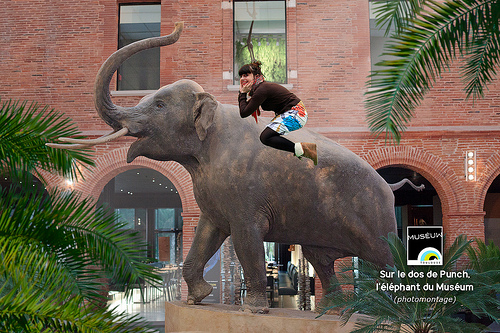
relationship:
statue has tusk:
[43, 23, 431, 316] [62, 129, 125, 146]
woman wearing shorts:
[237, 65, 320, 163] [272, 100, 308, 131]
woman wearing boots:
[237, 65, 320, 163] [302, 141, 322, 166]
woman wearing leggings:
[237, 65, 320, 163] [261, 127, 296, 153]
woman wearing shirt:
[237, 65, 320, 163] [236, 86, 302, 112]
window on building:
[235, 2, 286, 79] [3, 0, 499, 319]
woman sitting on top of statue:
[237, 65, 320, 163] [43, 23, 431, 316]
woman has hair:
[237, 65, 320, 163] [235, 59, 264, 80]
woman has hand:
[237, 65, 320, 163] [242, 83, 253, 92]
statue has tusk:
[43, 23, 431, 316] [43, 140, 81, 151]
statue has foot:
[43, 23, 431, 316] [189, 278, 217, 304]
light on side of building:
[467, 148, 476, 184] [3, 0, 499, 319]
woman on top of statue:
[237, 65, 320, 163] [43, 23, 431, 316]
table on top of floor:
[144, 262, 175, 293] [109, 284, 170, 319]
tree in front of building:
[3, 99, 162, 332] [3, 0, 499, 319]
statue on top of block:
[43, 23, 431, 316] [166, 295, 396, 331]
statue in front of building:
[43, 23, 431, 316] [3, 0, 499, 319]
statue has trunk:
[43, 23, 431, 316] [92, 22, 180, 123]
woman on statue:
[237, 60, 320, 163] [43, 23, 431, 316]